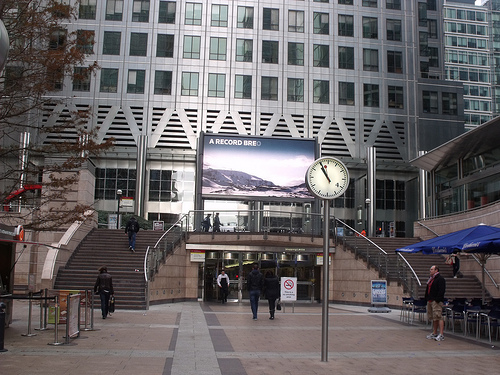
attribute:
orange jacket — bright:
[360, 225, 368, 237]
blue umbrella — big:
[396, 219, 498, 259]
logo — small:
[372, 277, 386, 307]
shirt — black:
[420, 269, 448, 305]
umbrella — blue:
[387, 217, 498, 266]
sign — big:
[187, 124, 331, 241]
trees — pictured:
[0, 0, 95, 231]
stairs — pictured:
[48, 218, 176, 308]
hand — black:
[314, 161, 334, 184]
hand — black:
[318, 167, 337, 187]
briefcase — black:
[103, 293, 116, 312]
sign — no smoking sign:
[271, 267, 302, 308]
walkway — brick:
[153, 290, 426, 374]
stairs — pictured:
[333, 218, 497, 313]